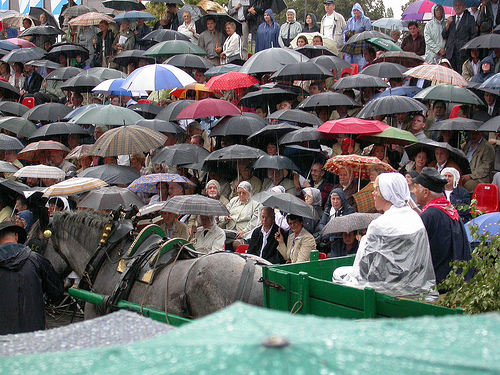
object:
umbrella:
[158, 192, 230, 228]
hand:
[187, 224, 199, 238]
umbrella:
[294, 89, 364, 110]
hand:
[296, 95, 307, 103]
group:
[0, 0, 499, 338]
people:
[272, 213, 317, 262]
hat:
[235, 179, 254, 200]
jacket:
[246, 222, 289, 265]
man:
[246, 204, 288, 267]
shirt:
[187, 225, 226, 259]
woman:
[330, 171, 439, 306]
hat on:
[375, 171, 411, 210]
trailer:
[259, 249, 462, 321]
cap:
[376, 170, 410, 209]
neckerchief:
[417, 195, 461, 222]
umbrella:
[117, 56, 198, 107]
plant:
[412, 192, 499, 316]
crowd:
[0, 0, 499, 336]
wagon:
[0, 299, 499, 375]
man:
[408, 165, 474, 295]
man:
[0, 220, 65, 337]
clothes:
[0, 239, 65, 336]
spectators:
[213, 20, 244, 64]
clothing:
[418, 203, 475, 292]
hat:
[409, 166, 449, 195]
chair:
[468, 180, 500, 216]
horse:
[21, 207, 276, 323]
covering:
[331, 204, 441, 305]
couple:
[244, 204, 316, 268]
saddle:
[115, 222, 199, 286]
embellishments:
[100, 221, 199, 317]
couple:
[330, 169, 477, 307]